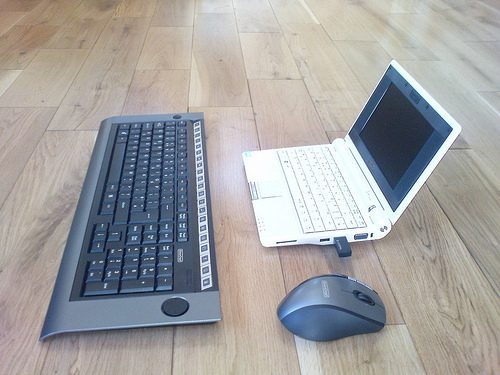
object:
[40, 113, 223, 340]
keyboard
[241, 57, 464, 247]
computer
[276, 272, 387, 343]
mouse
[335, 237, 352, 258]
usb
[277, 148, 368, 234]
keyboard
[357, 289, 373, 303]
wheel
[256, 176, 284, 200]
trackpad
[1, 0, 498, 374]
floor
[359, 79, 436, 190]
screen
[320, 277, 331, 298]
logo